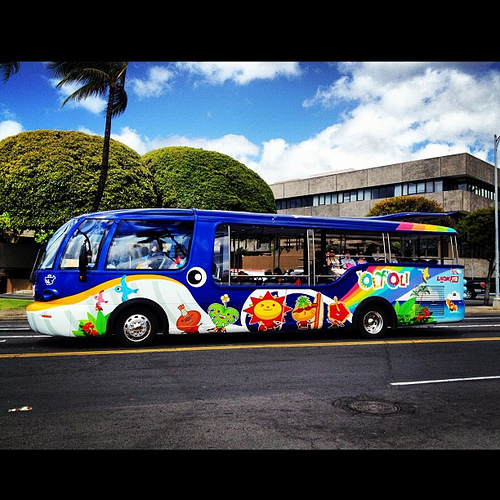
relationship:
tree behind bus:
[45, 62, 131, 211] [24, 207, 468, 347]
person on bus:
[330, 251, 342, 268] [24, 207, 468, 347]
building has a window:
[268, 154, 499, 290] [395, 183, 403, 198]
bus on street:
[24, 207, 468, 347] [2, 320, 499, 498]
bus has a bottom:
[24, 207, 468, 347] [29, 316, 469, 337]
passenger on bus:
[357, 251, 368, 265] [24, 207, 468, 347]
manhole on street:
[347, 397, 398, 416] [2, 320, 499, 498]